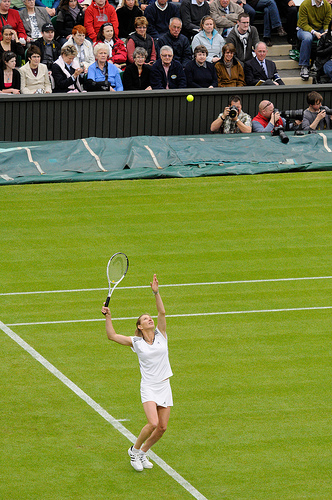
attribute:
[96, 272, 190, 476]
woman — throwing, playing, older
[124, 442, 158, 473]
shoes — white, light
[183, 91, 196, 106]
tennis ball — green, yellow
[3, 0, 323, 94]
crowd — large, watching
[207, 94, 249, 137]
photographer — three, black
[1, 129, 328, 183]
tarp — green, large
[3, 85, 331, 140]
railing — green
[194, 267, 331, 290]
line — white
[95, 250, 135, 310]
racket — white, black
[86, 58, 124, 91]
shirt — blue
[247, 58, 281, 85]
suit — dark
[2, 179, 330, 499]
grass — green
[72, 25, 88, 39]
hair — red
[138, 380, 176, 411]
skirt — white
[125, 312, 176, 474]
tennis player — serving, female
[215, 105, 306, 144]
cameras — large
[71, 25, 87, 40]
hair — bright red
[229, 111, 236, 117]
lens — telephoto